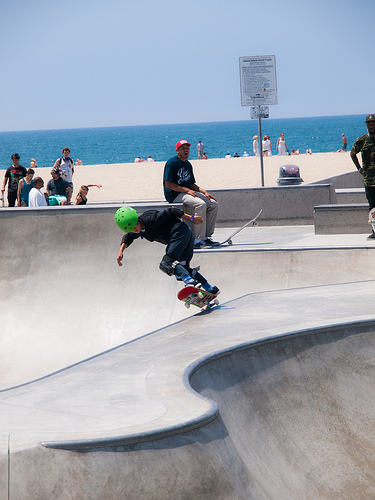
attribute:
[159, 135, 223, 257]
man — sitting, stepping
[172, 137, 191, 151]
hat — red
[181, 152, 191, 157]
mouth — open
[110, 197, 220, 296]
child — skateboarding, skateboardin, doing tricks, riding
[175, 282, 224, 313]
skateboard — red, white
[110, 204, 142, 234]
helmet — green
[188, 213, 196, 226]
watch — purple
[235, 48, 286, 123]
sign — black, white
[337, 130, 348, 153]
man — shirtless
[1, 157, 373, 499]
park — concrete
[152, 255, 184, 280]
guards — knee, black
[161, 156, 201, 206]
shirt — black, camoflage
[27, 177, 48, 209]
people — sitting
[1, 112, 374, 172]
ocean — blue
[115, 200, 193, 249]
shirt — black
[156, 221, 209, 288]
pants — black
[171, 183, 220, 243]
pants — tan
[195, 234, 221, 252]
shoes — black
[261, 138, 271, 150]
shirt — white